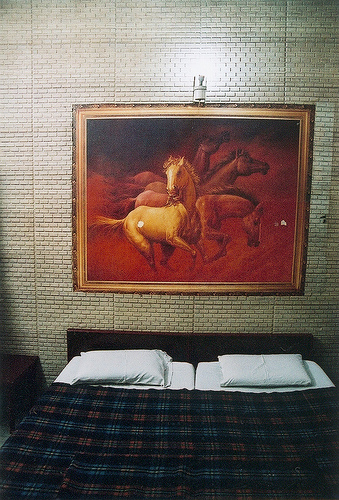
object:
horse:
[118, 147, 269, 200]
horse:
[163, 186, 265, 265]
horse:
[85, 155, 210, 276]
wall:
[3, 1, 337, 384]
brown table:
[1, 350, 44, 434]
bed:
[0, 324, 338, 499]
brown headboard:
[66, 331, 316, 359]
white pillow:
[217, 354, 310, 387]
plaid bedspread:
[1, 384, 337, 498]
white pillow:
[53, 349, 170, 385]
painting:
[70, 101, 314, 296]